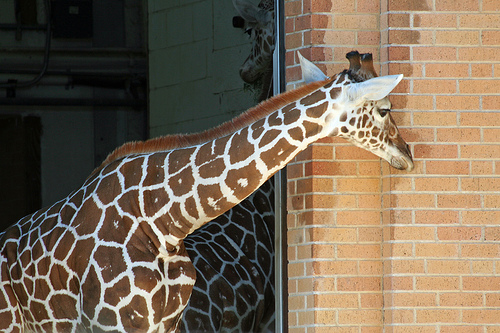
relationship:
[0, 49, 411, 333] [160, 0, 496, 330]
animal near building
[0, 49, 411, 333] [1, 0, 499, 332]
animal kissing building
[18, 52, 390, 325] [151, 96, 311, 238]
animal has neck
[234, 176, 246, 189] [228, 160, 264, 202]
spots in patch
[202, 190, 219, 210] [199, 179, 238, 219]
spots in patch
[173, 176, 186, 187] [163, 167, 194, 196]
spots in patch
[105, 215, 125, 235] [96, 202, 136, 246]
spots in patch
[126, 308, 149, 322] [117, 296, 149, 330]
spots in patch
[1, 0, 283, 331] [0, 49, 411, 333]
doorway with animal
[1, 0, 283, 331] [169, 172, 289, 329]
doorway with giraffe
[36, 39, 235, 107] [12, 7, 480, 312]
wall in building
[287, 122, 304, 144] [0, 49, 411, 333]
spot on animal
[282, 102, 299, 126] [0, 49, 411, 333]
spot on animal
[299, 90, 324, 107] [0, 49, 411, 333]
spot on animal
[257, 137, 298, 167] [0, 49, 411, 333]
spot on animal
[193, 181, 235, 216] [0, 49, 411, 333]
spot on animal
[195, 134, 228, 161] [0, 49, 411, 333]
spot on animal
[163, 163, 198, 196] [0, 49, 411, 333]
spot on animal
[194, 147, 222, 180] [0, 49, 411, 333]
spot on animal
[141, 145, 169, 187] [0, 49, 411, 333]
spot on animal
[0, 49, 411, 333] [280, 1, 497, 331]
animal outside of brick building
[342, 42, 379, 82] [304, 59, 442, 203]
ossicones on top of giraffe head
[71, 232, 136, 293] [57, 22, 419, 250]
brown spots on giraffe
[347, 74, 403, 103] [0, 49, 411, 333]
ear of animal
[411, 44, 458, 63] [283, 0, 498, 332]
red bricks on side of building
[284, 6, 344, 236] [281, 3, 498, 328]
stain on wall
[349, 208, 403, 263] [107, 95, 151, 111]
building behind bridge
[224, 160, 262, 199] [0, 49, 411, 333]
spot on animal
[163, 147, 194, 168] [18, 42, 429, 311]
spot on giraffe